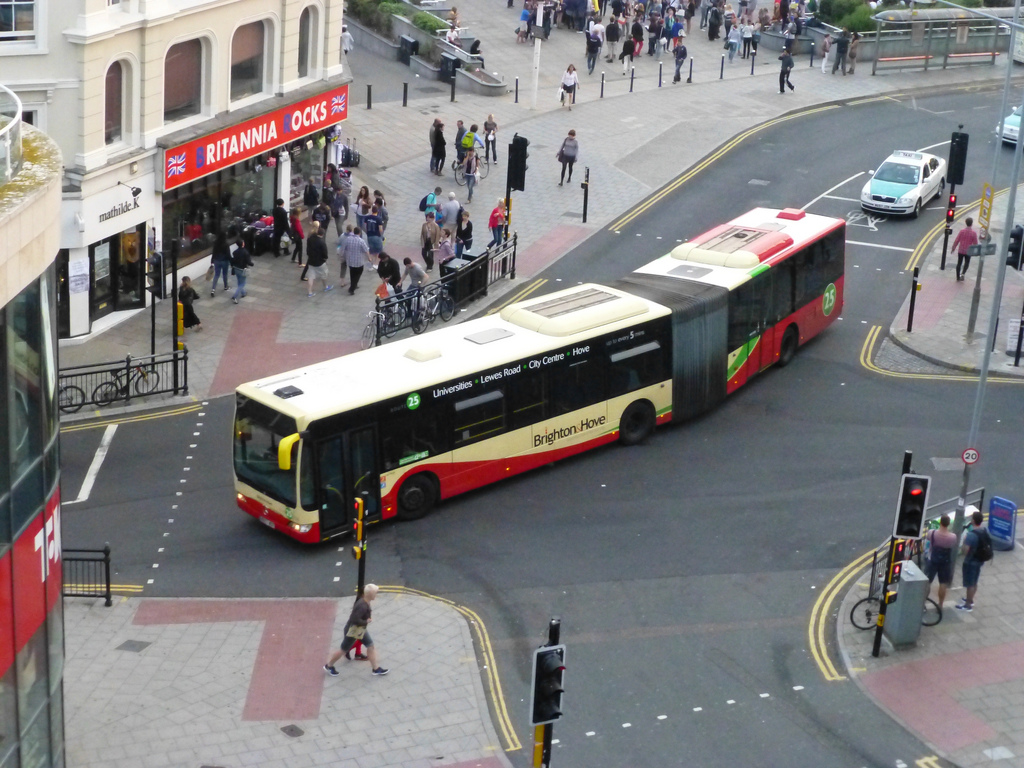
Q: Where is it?
A: This is at the street.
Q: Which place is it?
A: It is a street.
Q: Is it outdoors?
A: Yes, it is outdoors.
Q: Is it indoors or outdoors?
A: It is outdoors.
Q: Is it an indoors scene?
A: No, it is outdoors.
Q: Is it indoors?
A: No, it is outdoors.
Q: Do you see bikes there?
A: Yes, there is a bike.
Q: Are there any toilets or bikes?
A: Yes, there is a bike.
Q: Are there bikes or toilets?
A: Yes, there is a bike.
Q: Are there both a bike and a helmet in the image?
A: No, there is a bike but no helmets.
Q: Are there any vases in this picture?
A: No, there are no vases.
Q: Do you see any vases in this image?
A: No, there are no vases.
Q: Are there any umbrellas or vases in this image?
A: No, there are no vases or umbrellas.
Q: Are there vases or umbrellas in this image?
A: No, there are no vases or umbrellas.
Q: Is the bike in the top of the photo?
A: Yes, the bike is in the top of the image.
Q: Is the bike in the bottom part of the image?
A: No, the bike is in the top of the image.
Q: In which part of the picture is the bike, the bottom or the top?
A: The bike is in the top of the image.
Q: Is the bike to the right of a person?
A: No, the bike is to the left of a person.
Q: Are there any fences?
A: Yes, there is a fence.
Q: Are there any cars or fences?
A: Yes, there is a fence.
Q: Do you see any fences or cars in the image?
A: Yes, there is a fence.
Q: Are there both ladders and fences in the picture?
A: No, there is a fence but no ladders.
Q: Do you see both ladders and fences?
A: No, there is a fence but no ladders.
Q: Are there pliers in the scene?
A: No, there are no pliers.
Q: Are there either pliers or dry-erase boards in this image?
A: No, there are no pliers or dry-erase boards.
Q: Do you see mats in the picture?
A: No, there are no mats.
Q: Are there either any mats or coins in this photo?
A: No, there are no mats or coins.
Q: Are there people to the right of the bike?
A: Yes, there is a person to the right of the bike.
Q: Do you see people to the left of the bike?
A: No, the person is to the right of the bike.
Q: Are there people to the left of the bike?
A: No, the person is to the right of the bike.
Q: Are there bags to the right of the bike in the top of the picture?
A: No, there is a person to the right of the bike.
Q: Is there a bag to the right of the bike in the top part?
A: No, there is a person to the right of the bike.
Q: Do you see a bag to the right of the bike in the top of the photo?
A: No, there is a person to the right of the bike.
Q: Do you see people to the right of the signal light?
A: Yes, there is a person to the right of the signal light.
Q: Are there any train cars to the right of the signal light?
A: No, there is a person to the right of the signal light.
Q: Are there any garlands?
A: No, there are no garlands.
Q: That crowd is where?
A: The crowd is in the street.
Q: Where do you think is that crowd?
A: The crowd is in the street.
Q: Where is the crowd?
A: The crowd is in the street.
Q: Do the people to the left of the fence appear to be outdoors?
A: Yes, the people are outdoors.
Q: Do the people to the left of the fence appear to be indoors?
A: No, the people are outdoors.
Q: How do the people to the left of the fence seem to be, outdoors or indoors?
A: The people are outdoors.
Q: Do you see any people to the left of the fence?
A: Yes, there are people to the left of the fence.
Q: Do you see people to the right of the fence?
A: No, the people are to the left of the fence.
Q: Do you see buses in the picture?
A: Yes, there is a bus.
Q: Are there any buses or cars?
A: Yes, there is a bus.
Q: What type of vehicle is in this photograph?
A: The vehicle is a bus.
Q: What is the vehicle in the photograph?
A: The vehicle is a bus.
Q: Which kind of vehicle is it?
A: The vehicle is a bus.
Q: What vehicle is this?
A: That is a bus.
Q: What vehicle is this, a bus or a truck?
A: That is a bus.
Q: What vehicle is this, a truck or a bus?
A: That is a bus.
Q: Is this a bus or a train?
A: This is a bus.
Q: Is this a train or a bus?
A: This is a bus.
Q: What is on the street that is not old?
A: The bus is on the street.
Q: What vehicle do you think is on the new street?
A: The vehicle is a bus.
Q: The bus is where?
A: The bus is on the street.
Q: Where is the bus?
A: The bus is on the street.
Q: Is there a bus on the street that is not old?
A: Yes, there is a bus on the street.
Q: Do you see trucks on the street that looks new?
A: No, there is a bus on the street.